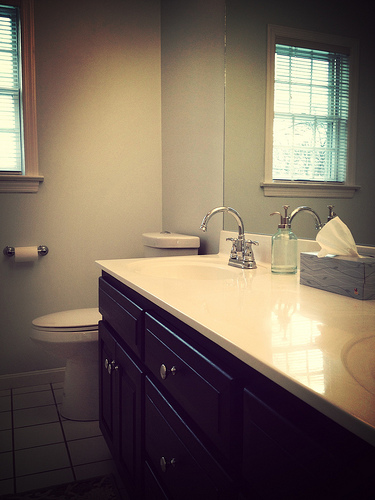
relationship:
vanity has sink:
[95, 229, 374, 447] [127, 259, 239, 284]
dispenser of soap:
[270, 205, 296, 276] [271, 238, 297, 274]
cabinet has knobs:
[97, 268, 374, 499] [102, 357, 179, 477]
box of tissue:
[297, 250, 374, 301] [316, 215, 366, 260]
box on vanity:
[297, 250, 374, 301] [95, 229, 374, 447]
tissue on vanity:
[316, 215, 366, 260] [95, 229, 374, 447]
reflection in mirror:
[260, 19, 359, 244] [223, 3, 374, 248]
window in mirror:
[260, 22, 360, 200] [223, 3, 374, 248]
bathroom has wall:
[0, 0, 373, 496] [0, 0, 162, 390]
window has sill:
[1, 3, 46, 195] [0, 175, 45, 197]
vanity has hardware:
[95, 229, 374, 447] [101, 357, 178, 473]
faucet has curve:
[199, 206, 259, 272] [200, 206, 244, 235]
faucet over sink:
[199, 206, 259, 272] [127, 259, 239, 284]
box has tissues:
[297, 250, 374, 301] [314, 215, 372, 263]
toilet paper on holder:
[13, 246, 40, 265] [4, 245, 47, 258]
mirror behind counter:
[223, 3, 374, 248] [95, 230, 372, 412]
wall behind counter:
[161, 0, 374, 269] [95, 230, 372, 412]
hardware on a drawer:
[158, 363, 176, 382] [142, 310, 236, 463]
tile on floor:
[3, 380, 359, 499] [1, 380, 126, 499]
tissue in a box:
[316, 215, 366, 260] [297, 250, 374, 301]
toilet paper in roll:
[13, 246, 40, 265] [14, 246, 39, 264]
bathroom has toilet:
[0, 0, 373, 496] [30, 230, 201, 424]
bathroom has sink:
[0, 0, 373, 496] [127, 259, 239, 284]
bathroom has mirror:
[0, 0, 373, 496] [223, 3, 374, 248]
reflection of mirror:
[260, 19, 359, 244] [223, 3, 374, 248]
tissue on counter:
[316, 215, 366, 260] [95, 230, 372, 412]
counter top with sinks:
[95, 229, 374, 447] [128, 256, 375, 399]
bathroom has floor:
[0, 0, 373, 496] [1, 380, 126, 499]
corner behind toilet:
[154, 0, 171, 234] [30, 230, 201, 424]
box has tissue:
[298, 250, 375, 302] [316, 215, 366, 260]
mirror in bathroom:
[223, 3, 374, 248] [0, 0, 373, 496]